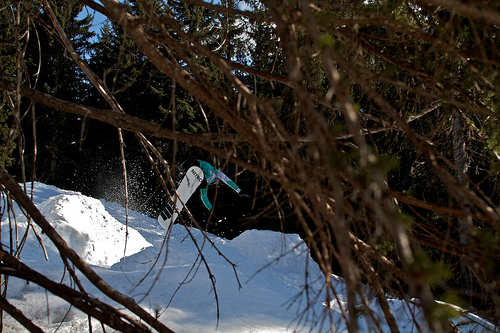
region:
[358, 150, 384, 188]
branches of a tree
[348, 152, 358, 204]
woody vegetation in a forest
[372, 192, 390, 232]
part of a branch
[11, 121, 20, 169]
leaves of a tree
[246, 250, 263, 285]
snowy white landscape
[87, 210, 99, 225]
section of a small hill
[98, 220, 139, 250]
part of a snowy surface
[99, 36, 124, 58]
section of a forest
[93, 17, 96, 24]
part of the sky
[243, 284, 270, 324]
bottom part of snow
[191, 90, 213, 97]
section of a branch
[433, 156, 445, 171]
part of a tree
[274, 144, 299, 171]
portion of a woody tree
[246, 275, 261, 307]
part of a snowy landscape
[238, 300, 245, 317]
white snowy surface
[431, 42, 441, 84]
leaves of a tree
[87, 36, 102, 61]
leaves of a tall tree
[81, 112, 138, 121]
extension of a tree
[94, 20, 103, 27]
portion of blue sky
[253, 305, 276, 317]
part of a white snowy surface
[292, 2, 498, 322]
thick brown brush with green leaves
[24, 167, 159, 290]
A pile of snow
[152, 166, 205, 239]
a white and black snowboard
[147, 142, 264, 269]
a snow boarder jumping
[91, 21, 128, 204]
a large green pine tree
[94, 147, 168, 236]
Snow scattered in air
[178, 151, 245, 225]
snow boarder in green and black suit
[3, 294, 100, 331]
hole in snow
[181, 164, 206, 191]
logo on bottom of snowboard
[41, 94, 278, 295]
snow boarder doing a trick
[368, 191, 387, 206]
branches of a tree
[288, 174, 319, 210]
wooden branches of a tree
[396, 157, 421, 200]
part of a woody tree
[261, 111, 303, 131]
section of a tree leaves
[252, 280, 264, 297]
white snowy landscape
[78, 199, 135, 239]
part of a snowy surface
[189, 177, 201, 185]
section of a bottle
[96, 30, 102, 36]
part of the blue sky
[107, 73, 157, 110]
section of a forest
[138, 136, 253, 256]
Person snowboarding in the woods.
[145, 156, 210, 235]
White and black snowboard.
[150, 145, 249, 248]
Snowboarder in the air.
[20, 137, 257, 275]
Snowboarder jumping off a jump.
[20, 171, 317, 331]
White snow on the ground.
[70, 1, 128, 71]
Clear blue sky.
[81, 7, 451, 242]
Branches without leaves on them.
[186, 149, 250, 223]
Person wearing a mint green jacket.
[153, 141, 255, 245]
Person with arms up in the air.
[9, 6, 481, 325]
Winter scene in the forest.